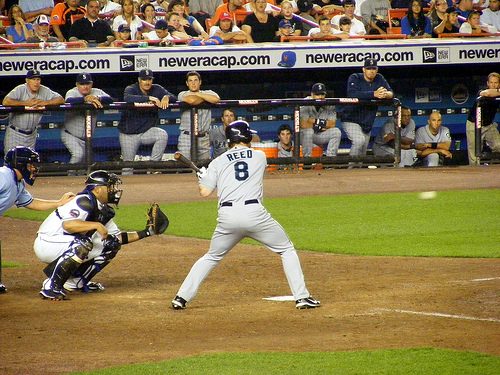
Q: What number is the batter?
A: 8.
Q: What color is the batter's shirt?
A: White.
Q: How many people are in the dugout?
A: 11.